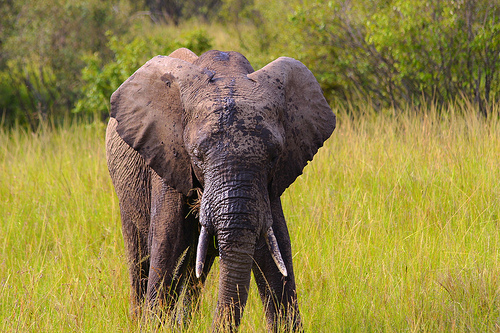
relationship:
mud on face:
[204, 83, 271, 147] [178, 88, 295, 210]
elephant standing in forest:
[90, 32, 351, 333] [5, 5, 486, 103]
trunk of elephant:
[204, 213, 266, 330] [90, 32, 351, 333]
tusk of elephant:
[190, 223, 212, 280] [90, 32, 351, 333]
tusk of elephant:
[257, 223, 296, 283] [90, 32, 351, 333]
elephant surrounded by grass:
[90, 32, 351, 333] [4, 262, 492, 333]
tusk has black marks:
[257, 223, 296, 283] [264, 228, 288, 269]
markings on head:
[199, 63, 244, 125] [173, 47, 293, 200]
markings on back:
[206, 43, 242, 69] [178, 44, 253, 71]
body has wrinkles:
[102, 134, 152, 219] [103, 141, 148, 190]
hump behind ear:
[178, 44, 253, 71] [101, 53, 190, 200]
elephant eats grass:
[90, 32, 351, 333] [4, 262, 492, 333]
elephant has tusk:
[90, 32, 351, 333] [190, 223, 212, 280]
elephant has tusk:
[90, 32, 351, 333] [257, 223, 296, 283]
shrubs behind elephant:
[3, 29, 491, 118] [90, 32, 351, 333]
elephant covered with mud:
[90, 32, 351, 333] [204, 83, 271, 147]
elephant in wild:
[90, 32, 351, 333] [6, 3, 495, 328]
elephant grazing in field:
[90, 32, 351, 333] [21, 126, 498, 332]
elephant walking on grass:
[90, 32, 351, 333] [4, 262, 492, 333]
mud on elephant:
[204, 83, 271, 147] [90, 32, 351, 333]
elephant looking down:
[90, 32, 351, 333] [4, 262, 492, 333]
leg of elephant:
[255, 223, 306, 331] [90, 32, 351, 333]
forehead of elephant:
[187, 92, 281, 142] [90, 32, 351, 333]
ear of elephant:
[101, 53, 190, 200] [90, 32, 351, 333]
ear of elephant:
[256, 48, 345, 200] [90, 32, 351, 333]